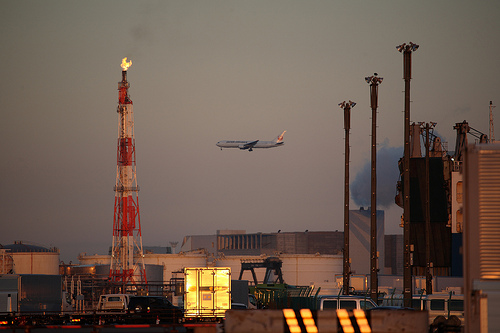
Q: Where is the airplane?
A: In the air.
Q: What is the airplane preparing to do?
A: Land.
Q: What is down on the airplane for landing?
A: Landing gear wheels.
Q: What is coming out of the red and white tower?
A: Fire.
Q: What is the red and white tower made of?
A: Metal.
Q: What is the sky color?
A: Grey.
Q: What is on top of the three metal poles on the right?
A: Lights.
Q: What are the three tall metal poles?
A: Lights.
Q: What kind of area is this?
A: An industrial area.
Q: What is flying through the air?
A: An airplane.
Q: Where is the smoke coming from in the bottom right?
A: The top of a building.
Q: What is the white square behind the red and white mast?
A: A white building.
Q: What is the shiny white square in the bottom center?
A: The back of a truck.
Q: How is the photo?
A: Clear.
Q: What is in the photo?
A: Plane.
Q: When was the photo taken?
A: Nighttime.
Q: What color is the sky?
A: White and blue.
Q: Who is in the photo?
A: Nobody.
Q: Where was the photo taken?
A: In the city.